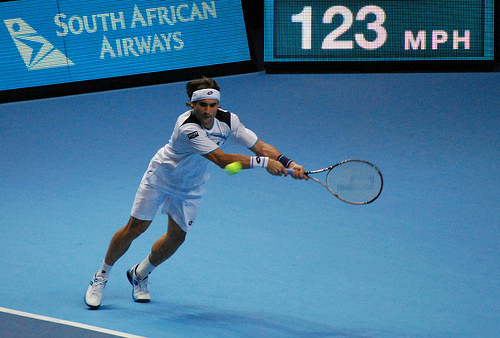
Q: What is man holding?
A: Racket.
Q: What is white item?
A: Headband.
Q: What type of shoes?
A: Tennis.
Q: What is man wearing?
A: White shirt.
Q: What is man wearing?
A: White shorts.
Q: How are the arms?
A: Stretching.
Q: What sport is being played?
A: Tennis.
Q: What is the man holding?
A: Racket.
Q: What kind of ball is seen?
A: Tennis ball.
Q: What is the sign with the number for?
A: Miles per hour.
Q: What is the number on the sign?
A: 123.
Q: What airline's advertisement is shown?
A: South African Airways.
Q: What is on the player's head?
A: Headband.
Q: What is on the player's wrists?
A: Wristbands.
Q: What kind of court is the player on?
A: Tennis court.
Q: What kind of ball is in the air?
A: Tennis ball.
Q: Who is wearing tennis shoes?
A: Player.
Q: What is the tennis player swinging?
A: Tennis racket.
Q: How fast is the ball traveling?
A: 123 MPH.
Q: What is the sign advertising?
A: South African Airways.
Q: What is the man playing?
A: Tennis.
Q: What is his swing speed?
A: 123 mph.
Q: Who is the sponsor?
A: South African Airways.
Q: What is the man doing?
A: Swinging a tennis racket.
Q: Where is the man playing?
A: On a tennis court.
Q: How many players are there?
A: One player is visible.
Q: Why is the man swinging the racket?
A: To hit the tennis ball.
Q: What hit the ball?
A: A tennis racket.